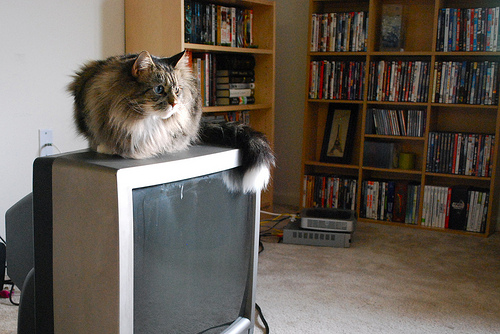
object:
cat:
[64, 47, 203, 161]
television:
[0, 146, 264, 334]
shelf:
[125, 0, 277, 218]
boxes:
[282, 221, 352, 248]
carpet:
[254, 202, 500, 333]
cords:
[265, 223, 279, 231]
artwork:
[325, 107, 352, 159]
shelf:
[299, 0, 500, 240]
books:
[215, 69, 256, 77]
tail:
[198, 117, 280, 197]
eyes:
[173, 85, 180, 92]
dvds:
[344, 9, 352, 52]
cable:
[261, 210, 299, 216]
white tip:
[240, 164, 271, 196]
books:
[215, 76, 256, 83]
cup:
[398, 152, 415, 170]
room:
[4, 0, 499, 331]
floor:
[0, 206, 500, 334]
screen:
[130, 164, 255, 334]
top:
[29, 138, 243, 178]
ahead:
[400, 0, 499, 333]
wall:
[2, 0, 126, 299]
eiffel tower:
[328, 123, 343, 153]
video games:
[389, 61, 394, 101]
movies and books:
[184, 1, 259, 107]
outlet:
[37, 125, 53, 157]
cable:
[51, 144, 62, 154]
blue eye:
[154, 84, 164, 94]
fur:
[64, 47, 277, 195]